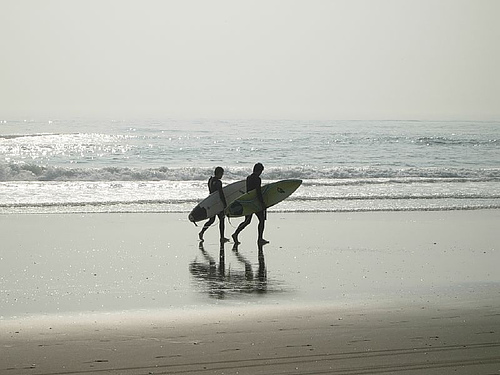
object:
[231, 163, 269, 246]
surfers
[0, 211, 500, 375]
beach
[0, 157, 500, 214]
wave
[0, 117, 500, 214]
water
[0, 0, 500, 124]
sky